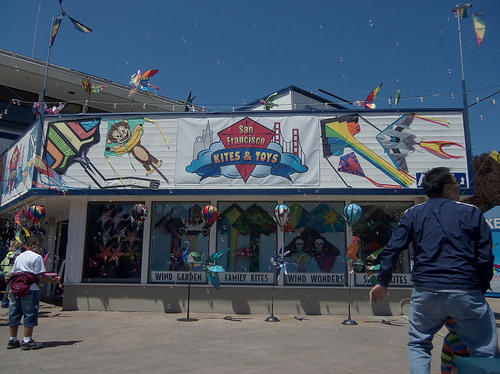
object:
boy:
[0, 236, 72, 352]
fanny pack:
[7, 273, 41, 296]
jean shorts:
[7, 290, 39, 327]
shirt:
[11, 251, 46, 291]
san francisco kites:
[212, 115, 281, 180]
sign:
[0, 109, 476, 211]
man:
[372, 167, 496, 374]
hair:
[420, 168, 452, 199]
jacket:
[381, 196, 493, 298]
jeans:
[407, 286, 499, 373]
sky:
[0, 0, 500, 160]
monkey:
[104, 117, 169, 182]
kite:
[320, 114, 414, 191]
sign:
[216, 201, 275, 286]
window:
[82, 200, 146, 283]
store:
[11, 108, 484, 341]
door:
[44, 218, 73, 300]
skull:
[311, 238, 328, 256]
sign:
[283, 201, 349, 288]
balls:
[26, 204, 47, 228]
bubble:
[368, 19, 374, 27]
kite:
[375, 112, 465, 170]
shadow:
[25, 335, 79, 353]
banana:
[106, 124, 143, 154]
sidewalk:
[0, 296, 500, 372]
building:
[228, 86, 352, 113]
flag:
[465, 6, 489, 46]